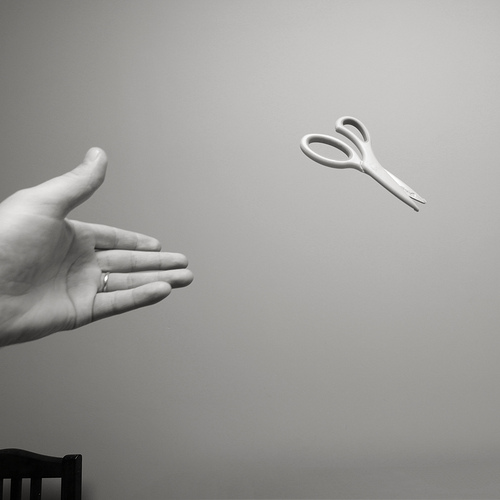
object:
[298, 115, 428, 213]
scissors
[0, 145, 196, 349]
hand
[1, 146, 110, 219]
thumb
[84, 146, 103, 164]
nail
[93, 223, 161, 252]
finger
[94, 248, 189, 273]
finger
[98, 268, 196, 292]
finger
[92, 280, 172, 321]
finger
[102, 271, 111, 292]
ring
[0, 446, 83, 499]
chair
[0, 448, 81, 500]
back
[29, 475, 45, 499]
rung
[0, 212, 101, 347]
palm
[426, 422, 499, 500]
corner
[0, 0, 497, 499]
wall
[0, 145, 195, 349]
person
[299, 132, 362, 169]
handle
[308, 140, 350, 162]
hole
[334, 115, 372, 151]
handle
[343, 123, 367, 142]
hole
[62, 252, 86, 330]
line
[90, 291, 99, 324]
line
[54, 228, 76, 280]
line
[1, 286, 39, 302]
line